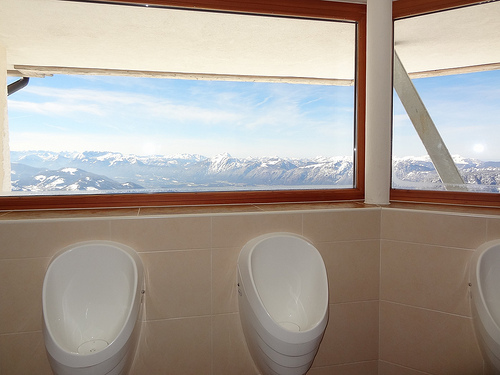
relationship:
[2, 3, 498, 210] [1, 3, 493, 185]
frame of window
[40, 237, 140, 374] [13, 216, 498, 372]
urinal attached to wall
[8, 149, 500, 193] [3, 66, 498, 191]
mountains on outside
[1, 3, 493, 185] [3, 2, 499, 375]
window in bathroom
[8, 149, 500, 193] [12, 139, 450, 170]
mountains capped with snow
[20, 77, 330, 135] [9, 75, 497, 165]
clouds in sky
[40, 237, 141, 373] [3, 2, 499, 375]
urinal in bathroom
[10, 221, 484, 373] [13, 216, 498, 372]
grout between tiles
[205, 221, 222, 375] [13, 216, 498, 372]
crack in wall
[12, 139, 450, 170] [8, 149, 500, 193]
peak of mountains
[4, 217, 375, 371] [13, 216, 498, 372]
part of a wall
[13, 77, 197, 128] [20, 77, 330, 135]
part of a clouds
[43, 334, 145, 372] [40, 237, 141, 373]
part of a urinal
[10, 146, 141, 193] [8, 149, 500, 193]
part of mountains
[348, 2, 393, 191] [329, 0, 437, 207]
part of a corner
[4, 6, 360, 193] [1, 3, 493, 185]
part of a window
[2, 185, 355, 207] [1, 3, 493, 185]
edge of a window